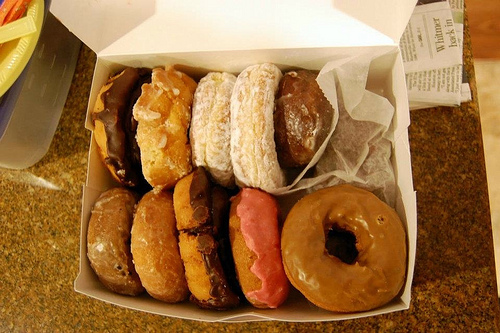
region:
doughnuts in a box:
[70, 61, 402, 303]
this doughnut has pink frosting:
[238, 187, 282, 302]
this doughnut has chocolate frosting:
[100, 56, 142, 179]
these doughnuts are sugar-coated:
[192, 68, 277, 180]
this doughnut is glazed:
[89, 192, 128, 282]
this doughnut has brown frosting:
[272, 179, 413, 309]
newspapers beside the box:
[407, 0, 483, 115]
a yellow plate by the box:
[0, 0, 47, 102]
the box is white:
[51, 3, 422, 57]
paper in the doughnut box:
[305, 62, 390, 187]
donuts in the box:
[67, 73, 421, 330]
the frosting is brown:
[277, 195, 406, 311]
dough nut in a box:
[285, 186, 406, 306]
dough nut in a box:
[235, 183, 282, 299]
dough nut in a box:
[175, 170, 222, 296]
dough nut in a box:
[137, 198, 178, 296]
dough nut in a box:
[91, 185, 128, 288]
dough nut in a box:
[91, 66, 132, 177]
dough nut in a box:
[135, 60, 187, 175]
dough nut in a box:
[235, 51, 280, 181]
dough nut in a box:
[275, 57, 325, 153]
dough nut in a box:
[192, 66, 231, 168]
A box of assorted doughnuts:
[76, 35, 427, 325]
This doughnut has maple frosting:
[278, 180, 400, 307]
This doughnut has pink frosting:
[233, 189, 293, 311]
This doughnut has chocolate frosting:
[91, 63, 137, 188]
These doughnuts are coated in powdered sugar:
[187, 67, 279, 189]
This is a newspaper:
[419, 4, 472, 110]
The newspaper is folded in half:
[420, 13, 476, 110]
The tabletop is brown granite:
[21, 185, 74, 317]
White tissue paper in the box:
[303, 0, 405, 184]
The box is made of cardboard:
[248, 34, 399, 80]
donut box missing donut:
[63, 0, 431, 326]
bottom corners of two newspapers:
[396, 0, 493, 131]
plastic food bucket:
[0, 0, 91, 189]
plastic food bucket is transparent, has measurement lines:
[0, 44, 40, 143]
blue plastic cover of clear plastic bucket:
[0, 70, 37, 151]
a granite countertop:
[0, 36, 499, 331]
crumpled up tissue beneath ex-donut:
[274, 59, 406, 197]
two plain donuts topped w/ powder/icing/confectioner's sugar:
[184, 56, 284, 195]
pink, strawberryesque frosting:
[239, 179, 293, 314]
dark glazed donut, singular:
[83, 185, 138, 297]